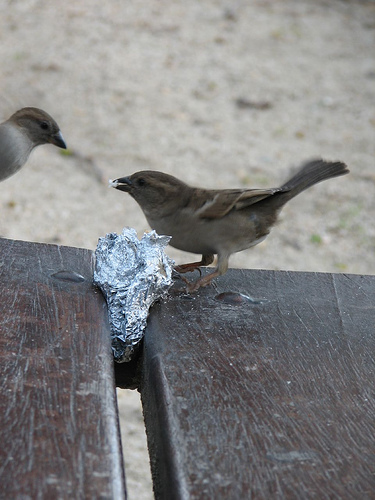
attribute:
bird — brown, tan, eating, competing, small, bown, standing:
[106, 155, 351, 296]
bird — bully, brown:
[1, 106, 68, 180]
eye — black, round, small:
[134, 176, 148, 188]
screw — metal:
[50, 269, 88, 283]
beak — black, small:
[110, 177, 132, 192]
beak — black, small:
[50, 132, 69, 150]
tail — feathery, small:
[274, 155, 351, 204]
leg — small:
[185, 252, 232, 299]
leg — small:
[168, 249, 215, 276]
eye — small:
[38, 121, 50, 132]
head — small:
[113, 170, 172, 201]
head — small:
[12, 106, 70, 151]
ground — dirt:
[3, 4, 372, 498]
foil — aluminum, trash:
[90, 231, 172, 367]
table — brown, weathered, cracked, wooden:
[3, 233, 374, 498]